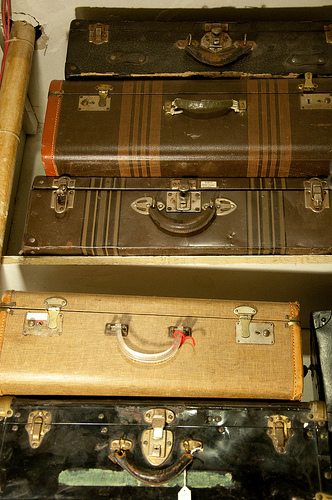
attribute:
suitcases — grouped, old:
[1, 2, 330, 500]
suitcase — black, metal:
[1, 393, 331, 500]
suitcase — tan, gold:
[2, 288, 307, 403]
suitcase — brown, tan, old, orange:
[38, 76, 331, 173]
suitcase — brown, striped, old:
[26, 173, 331, 261]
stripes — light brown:
[78, 180, 285, 253]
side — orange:
[41, 74, 68, 174]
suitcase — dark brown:
[66, 10, 330, 78]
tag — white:
[173, 466, 194, 500]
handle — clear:
[117, 320, 186, 371]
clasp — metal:
[22, 408, 54, 450]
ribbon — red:
[175, 325, 196, 350]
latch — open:
[139, 411, 173, 469]